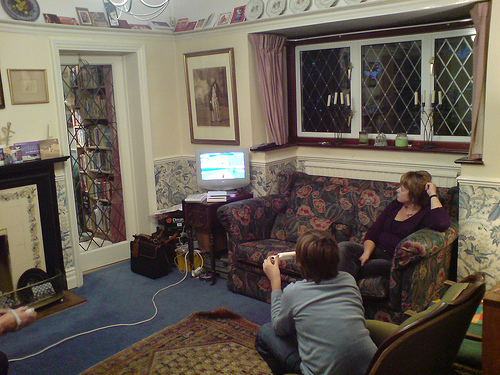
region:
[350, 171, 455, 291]
a woman sitting on a couch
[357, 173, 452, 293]
a woman wearing a purple shirt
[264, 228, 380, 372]
a person wearing a grey shirt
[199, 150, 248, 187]
the screen of the television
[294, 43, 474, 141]
the window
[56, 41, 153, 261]
a door of the room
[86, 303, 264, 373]
a rug on the floor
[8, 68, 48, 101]
a picture hanging on the wall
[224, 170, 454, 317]
a floral print couch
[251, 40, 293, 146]
curtains hanging by the window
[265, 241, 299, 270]
the controller in the hands of the boy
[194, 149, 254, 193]
the tv on the table by the couch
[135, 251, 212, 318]
the white chord on the ground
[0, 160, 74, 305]
the fireplace on the wall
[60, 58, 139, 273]
the doorway to the other room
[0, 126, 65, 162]
the cards on the fireplace mantle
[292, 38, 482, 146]
the window over the couch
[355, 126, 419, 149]
the candles on the frame of the window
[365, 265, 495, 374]
the brown leather back of the chair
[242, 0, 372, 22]
the plates on the mantle on the wall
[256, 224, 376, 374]
a boy sitting on a chair, playing a game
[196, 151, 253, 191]
a computer monitor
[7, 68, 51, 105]
a plaque on the wall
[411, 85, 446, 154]
a fancy candle holder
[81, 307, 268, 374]
an area rug on the floor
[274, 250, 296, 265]
a white remote control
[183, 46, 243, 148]
a picture hanging on the wall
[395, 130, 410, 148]
a small candle sitting in the window sill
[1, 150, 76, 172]
a mantle of a fireplace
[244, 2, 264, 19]
a decorative plate on the wall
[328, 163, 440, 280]
Woman sat on sofa.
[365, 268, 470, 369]
Green and wooden chair.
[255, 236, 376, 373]
Person sitting on green chair.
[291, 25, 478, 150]
Three windows with candles in front of it.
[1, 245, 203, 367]
Long white cord on floor.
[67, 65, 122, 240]
Book cases on other side of door.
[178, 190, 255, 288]
Dark brown wooden side table.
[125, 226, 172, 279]
Black and brown bag on floor.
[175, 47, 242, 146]
Picture of man in gold frame.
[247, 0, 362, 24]
A row of dishes above windows.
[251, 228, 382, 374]
Person watching the TV while sitting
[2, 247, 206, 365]
White wire on the ground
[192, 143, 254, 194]
White TV on the table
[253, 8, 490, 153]
White framed window behind a woman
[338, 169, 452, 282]
Woman sitting near the window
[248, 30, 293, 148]
Opened light red window cover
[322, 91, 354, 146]
Candles near the window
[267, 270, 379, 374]
Blue long sleeve t shirt worn by man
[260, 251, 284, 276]
Mann's hand holding a controller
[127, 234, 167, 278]
Black bag next to the table